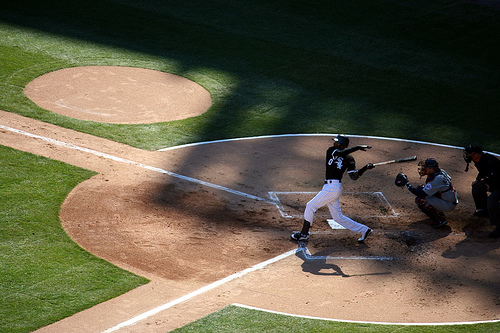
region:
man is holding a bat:
[312, 132, 447, 204]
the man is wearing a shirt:
[312, 142, 364, 181]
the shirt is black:
[318, 140, 364, 177]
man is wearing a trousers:
[299, 163, 370, 265]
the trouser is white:
[308, 171, 363, 248]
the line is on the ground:
[175, 274, 241, 291]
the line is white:
[170, 285, 235, 308]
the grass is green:
[18, 226, 78, 314]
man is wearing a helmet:
[327, 129, 355, 148]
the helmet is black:
[323, 130, 352, 148]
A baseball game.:
[132, 88, 497, 295]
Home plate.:
[325, 215, 350, 235]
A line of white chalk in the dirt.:
[0, 115, 230, 185]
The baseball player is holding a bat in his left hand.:
[271, 77, 416, 262]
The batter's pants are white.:
[285, 177, 375, 267]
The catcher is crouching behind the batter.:
[270, 105, 460, 236]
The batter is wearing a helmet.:
[315, 120, 350, 155]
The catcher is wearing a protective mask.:
[390, 145, 456, 235]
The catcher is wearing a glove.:
[390, 165, 415, 195]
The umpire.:
[455, 132, 496, 210]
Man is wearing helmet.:
[327, 130, 353, 155]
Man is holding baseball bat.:
[361, 155, 416, 175]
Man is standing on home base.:
[285, 127, 393, 257]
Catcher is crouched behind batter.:
[390, 147, 466, 240]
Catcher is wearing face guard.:
[413, 157, 440, 181]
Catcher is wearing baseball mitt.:
[390, 168, 410, 195]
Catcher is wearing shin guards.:
[411, 192, 453, 224]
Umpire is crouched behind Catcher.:
[458, 139, 499, 227]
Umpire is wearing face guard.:
[453, 138, 484, 168]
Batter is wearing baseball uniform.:
[296, 146, 373, 246]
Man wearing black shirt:
[311, 147, 356, 199]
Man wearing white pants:
[298, 192, 371, 230]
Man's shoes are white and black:
[281, 221, 328, 256]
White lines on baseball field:
[123, 257, 250, 312]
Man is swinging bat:
[288, 73, 404, 270]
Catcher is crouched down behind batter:
[381, 141, 440, 249]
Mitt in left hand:
[393, 160, 405, 202]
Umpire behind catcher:
[451, 128, 491, 168]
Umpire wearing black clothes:
[471, 162, 498, 264]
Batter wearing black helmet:
[321, 133, 353, 155]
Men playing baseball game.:
[110, 37, 495, 305]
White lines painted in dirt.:
[24, 115, 266, 215]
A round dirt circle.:
[22, 45, 217, 129]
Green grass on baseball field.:
[8, 163, 60, 306]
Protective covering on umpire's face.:
[455, 141, 499, 170]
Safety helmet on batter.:
[322, 130, 351, 153]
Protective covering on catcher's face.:
[405, 153, 460, 179]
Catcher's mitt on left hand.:
[391, 165, 411, 195]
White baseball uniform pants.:
[292, 174, 384, 241]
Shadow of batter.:
[286, 241, 381, 279]